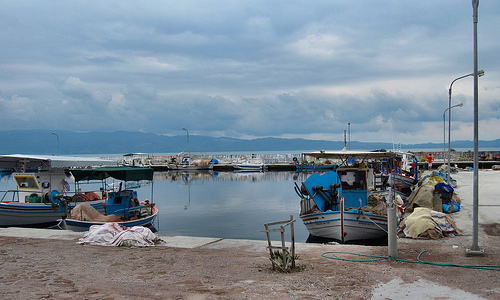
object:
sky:
[0, 0, 499, 145]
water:
[222, 184, 287, 222]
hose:
[321, 249, 500, 272]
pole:
[472, 0, 481, 256]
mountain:
[0, 127, 499, 155]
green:
[99, 152, 164, 164]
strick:
[258, 214, 300, 273]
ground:
[0, 226, 499, 299]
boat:
[62, 167, 159, 232]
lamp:
[447, 69, 484, 184]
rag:
[75, 221, 158, 248]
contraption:
[381, 185, 399, 257]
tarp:
[66, 164, 157, 182]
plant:
[265, 244, 299, 273]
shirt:
[426, 156, 432, 163]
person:
[425, 152, 435, 172]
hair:
[428, 153, 432, 157]